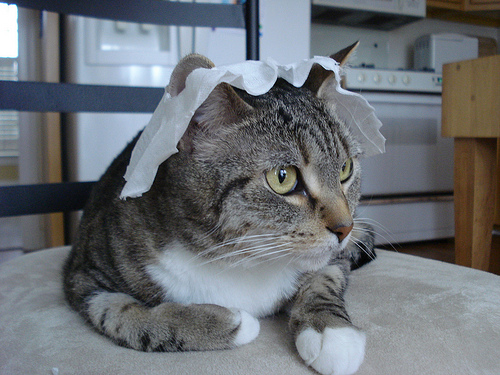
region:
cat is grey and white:
[106, 77, 383, 358]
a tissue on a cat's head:
[110, 37, 412, 177]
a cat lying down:
[45, 70, 403, 367]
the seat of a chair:
[36, 188, 421, 373]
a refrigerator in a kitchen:
[73, 17, 258, 184]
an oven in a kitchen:
[335, 45, 484, 241]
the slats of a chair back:
[10, 2, 300, 197]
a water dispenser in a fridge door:
[70, 7, 180, 57]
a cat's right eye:
[253, 148, 305, 202]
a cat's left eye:
[327, 142, 362, 189]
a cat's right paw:
[188, 302, 260, 352]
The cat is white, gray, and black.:
[82, 27, 419, 362]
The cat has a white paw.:
[291, 325, 367, 371]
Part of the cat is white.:
[166, 263, 292, 300]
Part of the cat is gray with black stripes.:
[263, 115, 341, 153]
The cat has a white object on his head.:
[108, 35, 398, 221]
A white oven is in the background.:
[345, 47, 466, 248]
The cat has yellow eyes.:
[260, 140, 366, 195]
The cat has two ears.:
[151, 20, 366, 111]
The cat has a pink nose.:
[316, 210, 364, 250]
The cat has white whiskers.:
[187, 219, 302, 295]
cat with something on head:
[184, 49, 394, 246]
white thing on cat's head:
[146, 40, 373, 185]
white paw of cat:
[289, 308, 371, 373]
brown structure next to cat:
[429, 51, 494, 253]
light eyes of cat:
[234, 139, 385, 206]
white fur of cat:
[173, 238, 256, 300]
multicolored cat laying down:
[125, 74, 380, 357]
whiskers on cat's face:
[209, 220, 324, 282]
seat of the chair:
[378, 243, 458, 348]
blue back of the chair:
[60, 69, 136, 138]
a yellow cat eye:
[254, 143, 306, 200]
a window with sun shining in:
[0, 0, 19, 57]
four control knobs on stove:
[351, 71, 418, 86]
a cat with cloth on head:
[100, 39, 407, 254]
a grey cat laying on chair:
[51, 33, 498, 373]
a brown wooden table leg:
[453, 136, 498, 271]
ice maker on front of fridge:
[86, 14, 174, 59]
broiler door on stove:
[356, 194, 461, 241]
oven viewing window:
[364, 108, 449, 151]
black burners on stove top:
[351, 59, 439, 73]